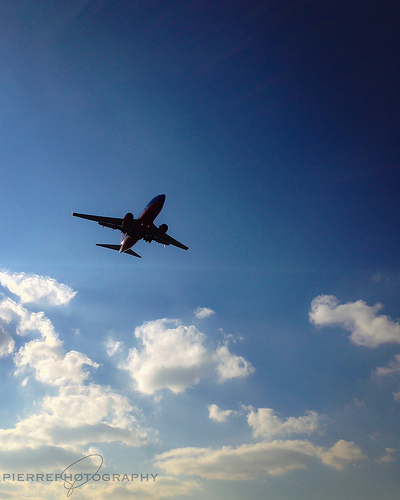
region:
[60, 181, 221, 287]
underside of airplane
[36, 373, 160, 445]
white cloud in the sky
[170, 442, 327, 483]
cloud with a shadow on it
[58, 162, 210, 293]
airplane flying in the sky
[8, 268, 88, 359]
sun shining on the clouds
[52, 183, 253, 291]
airplane as seen from the ground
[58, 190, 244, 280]
airplane flying away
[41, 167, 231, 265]
airplane in a cloudless sky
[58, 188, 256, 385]
airplane amidst the clouds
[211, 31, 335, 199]
dark blue patch of sky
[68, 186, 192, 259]
a plane in the sky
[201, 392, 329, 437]
a white cloud in the sky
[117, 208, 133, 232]
an engine on the plane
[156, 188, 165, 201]
the nose of a plane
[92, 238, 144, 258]
the tail of the plane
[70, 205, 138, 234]
a wing of the plane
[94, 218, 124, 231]
a flap on the plane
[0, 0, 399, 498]
a blue sky with clouds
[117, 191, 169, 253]
the body of the plane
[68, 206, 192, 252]
both wings of the plane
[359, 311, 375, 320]
section of the cloud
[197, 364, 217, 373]
part of a cloud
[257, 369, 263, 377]
section of the sky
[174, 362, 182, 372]
a dark grey cloud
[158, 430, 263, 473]
a group of dark clouds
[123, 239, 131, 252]
back of aplane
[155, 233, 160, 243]
right wing of a plane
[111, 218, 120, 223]
left wing of a plane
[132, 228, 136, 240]
bottom of a plane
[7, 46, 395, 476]
an airplane ascending into the sky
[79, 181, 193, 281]
a red colored airplane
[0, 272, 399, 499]
white clouds in the sky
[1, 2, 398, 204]
a deep blue sky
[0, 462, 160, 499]
a logo that says pierrepphotography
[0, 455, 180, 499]
a transluscent logo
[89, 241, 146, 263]
the triangular tail of a plane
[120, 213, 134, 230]
the engine of a plane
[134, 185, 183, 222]
the nose of a plane pointing upwards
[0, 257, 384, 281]
a faint white line in the sky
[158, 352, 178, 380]
part of a cloud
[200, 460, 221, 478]
part of a dark cloud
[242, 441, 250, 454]
section of a grey cloud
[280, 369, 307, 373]
part of a blue sky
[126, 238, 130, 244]
bottom of a plane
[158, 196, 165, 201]
front part of a plane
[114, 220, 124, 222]
right wing of a plane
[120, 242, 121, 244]
back part of a plane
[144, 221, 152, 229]
lights on a palne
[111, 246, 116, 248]
back wing of a plane